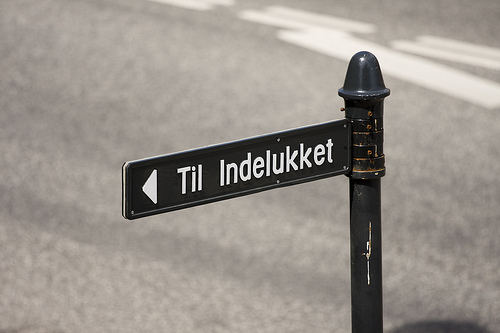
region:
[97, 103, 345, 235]
white lettering on black sign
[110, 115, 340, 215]
arrow on end of sign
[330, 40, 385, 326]
black pole supporting sign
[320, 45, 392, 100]
domed cap on top of pole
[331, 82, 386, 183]
part of pole attached to sign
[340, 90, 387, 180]
rusty dots and lines on pole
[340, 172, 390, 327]
long section of pole with white vertical line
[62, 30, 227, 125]
paving in light and medium grays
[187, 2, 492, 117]
thick white line and short double lines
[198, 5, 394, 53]
merging of thick and thin lines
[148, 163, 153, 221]
the arrow is white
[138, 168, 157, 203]
the arrow is white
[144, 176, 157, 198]
the arrow is white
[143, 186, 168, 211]
the arrow is white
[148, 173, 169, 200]
the arrow is white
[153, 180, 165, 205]
the arrow is white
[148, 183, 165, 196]
the arrow is white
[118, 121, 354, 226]
a black street sign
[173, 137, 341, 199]
white writing on the sign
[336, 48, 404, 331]
a black metal pole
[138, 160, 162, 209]
a white arrow on the sign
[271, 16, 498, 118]
a white line in the street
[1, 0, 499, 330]
a gray paved road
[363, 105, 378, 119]
an orange screw on the pole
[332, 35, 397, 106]
the tip of the pole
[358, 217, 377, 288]
a scratch on the sign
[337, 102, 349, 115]
a screw extending from the pole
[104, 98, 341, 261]
Black and white sign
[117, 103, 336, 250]
Black sign with white letters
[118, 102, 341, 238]
The sign reads Til Indelukket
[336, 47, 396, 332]
The pole is black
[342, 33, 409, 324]
The pole is tall and thin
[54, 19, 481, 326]
The ground is asphalt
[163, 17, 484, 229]
The ground has white lines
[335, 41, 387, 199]
There is brown rust on the pole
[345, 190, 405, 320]
The pole has a white scratch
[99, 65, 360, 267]
The sign points to the left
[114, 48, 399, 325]
Sign post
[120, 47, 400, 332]
Black sign post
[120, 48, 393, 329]
Sign post with white letters written on it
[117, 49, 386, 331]
Sign post with letter Til Indelukket written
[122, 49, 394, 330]
Sign post showing directions on the left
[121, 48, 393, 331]
Sign post made of metal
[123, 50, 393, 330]
Sign post on the side of the road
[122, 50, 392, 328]
Sign post on a deserted road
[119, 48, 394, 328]
White letters written on the sign post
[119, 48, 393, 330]
The sign post showing directions to the left